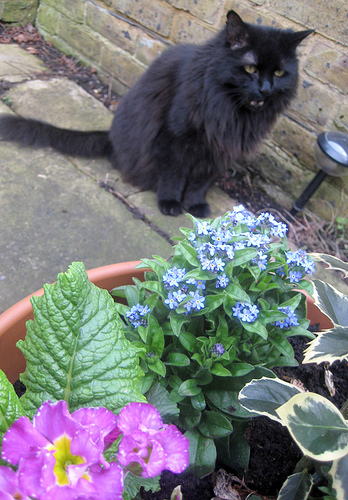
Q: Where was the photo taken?
A: It was taken at the patio.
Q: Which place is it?
A: It is a patio.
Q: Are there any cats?
A: Yes, there is a cat.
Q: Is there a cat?
A: Yes, there is a cat.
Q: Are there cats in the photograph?
A: Yes, there is a cat.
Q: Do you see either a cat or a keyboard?
A: Yes, there is a cat.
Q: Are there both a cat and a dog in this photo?
A: No, there is a cat but no dogs.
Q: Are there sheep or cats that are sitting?
A: Yes, the cat is sitting.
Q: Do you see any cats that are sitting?
A: Yes, there is a cat that is sitting.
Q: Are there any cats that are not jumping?
A: Yes, there is a cat that is sitting.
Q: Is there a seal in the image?
A: No, there are no seals.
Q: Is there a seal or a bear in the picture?
A: No, there are no seals or bears.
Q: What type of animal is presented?
A: The animal is a cat.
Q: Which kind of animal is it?
A: The animal is a cat.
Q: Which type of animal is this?
A: This is a cat.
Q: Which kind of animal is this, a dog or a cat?
A: This is a cat.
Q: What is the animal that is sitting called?
A: The animal is a cat.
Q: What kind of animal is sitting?
A: The animal is a cat.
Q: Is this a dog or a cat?
A: This is a cat.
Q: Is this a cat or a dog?
A: This is a cat.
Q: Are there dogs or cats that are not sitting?
A: No, there is a cat but it is sitting.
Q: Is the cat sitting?
A: Yes, the cat is sitting.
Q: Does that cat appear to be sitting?
A: Yes, the cat is sitting.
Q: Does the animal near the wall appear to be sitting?
A: Yes, the cat is sitting.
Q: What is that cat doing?
A: The cat is sitting.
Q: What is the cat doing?
A: The cat is sitting.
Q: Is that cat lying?
A: No, the cat is sitting.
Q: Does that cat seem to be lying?
A: No, the cat is sitting.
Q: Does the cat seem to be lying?
A: No, the cat is sitting.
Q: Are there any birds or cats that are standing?
A: No, there is a cat but it is sitting.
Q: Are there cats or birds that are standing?
A: No, there is a cat but it is sitting.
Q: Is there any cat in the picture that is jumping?
A: No, there is a cat but it is sitting.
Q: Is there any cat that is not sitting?
A: No, there is a cat but it is sitting.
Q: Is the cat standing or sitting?
A: The cat is sitting.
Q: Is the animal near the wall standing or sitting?
A: The cat is sitting.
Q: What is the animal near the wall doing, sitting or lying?
A: The cat is sitting.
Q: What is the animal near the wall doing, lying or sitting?
A: The cat is sitting.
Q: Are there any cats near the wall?
A: Yes, there is a cat near the wall.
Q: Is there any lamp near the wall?
A: No, there is a cat near the wall.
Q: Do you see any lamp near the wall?
A: No, there is a cat near the wall.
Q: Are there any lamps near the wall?
A: No, there is a cat near the wall.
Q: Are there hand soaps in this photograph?
A: No, there are no hand soaps.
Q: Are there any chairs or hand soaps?
A: No, there are no hand soaps or chairs.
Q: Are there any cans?
A: No, there are no cans.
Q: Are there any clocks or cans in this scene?
A: No, there are no cans or clocks.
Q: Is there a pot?
A: Yes, there is a pot.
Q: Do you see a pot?
A: Yes, there is a pot.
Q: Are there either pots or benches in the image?
A: Yes, there is a pot.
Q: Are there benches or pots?
A: Yes, there is a pot.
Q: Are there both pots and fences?
A: No, there is a pot but no fences.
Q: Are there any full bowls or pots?
A: Yes, there is a full pot.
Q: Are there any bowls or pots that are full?
A: Yes, the pot is full.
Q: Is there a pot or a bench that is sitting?
A: Yes, the pot is sitting.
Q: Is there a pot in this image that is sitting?
A: Yes, there is a pot that is sitting.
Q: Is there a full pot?
A: Yes, there is a full pot.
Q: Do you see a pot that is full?
A: Yes, there is a pot that is full.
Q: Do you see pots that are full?
A: Yes, there is a pot that is full.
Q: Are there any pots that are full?
A: Yes, there is a pot that is full.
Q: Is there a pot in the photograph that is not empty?
A: Yes, there is an full pot.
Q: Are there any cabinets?
A: No, there are no cabinets.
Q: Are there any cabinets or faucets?
A: No, there are no cabinets or faucets.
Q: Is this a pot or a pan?
A: This is a pot.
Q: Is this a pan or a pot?
A: This is a pot.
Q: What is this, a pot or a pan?
A: This is a pot.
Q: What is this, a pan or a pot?
A: This is a pot.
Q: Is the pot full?
A: Yes, the pot is full.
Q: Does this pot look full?
A: Yes, the pot is full.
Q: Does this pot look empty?
A: No, the pot is full.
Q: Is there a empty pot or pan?
A: No, there is a pot but it is full.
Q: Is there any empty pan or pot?
A: No, there is a pot but it is full.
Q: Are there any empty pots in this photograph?
A: No, there is a pot but it is full.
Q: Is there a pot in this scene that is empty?
A: No, there is a pot but it is full.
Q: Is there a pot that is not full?
A: No, there is a pot but it is full.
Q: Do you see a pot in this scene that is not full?
A: No, there is a pot but it is full.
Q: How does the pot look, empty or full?
A: The pot is full.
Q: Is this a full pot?
A: Yes, this is a full pot.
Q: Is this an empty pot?
A: No, this is a full pot.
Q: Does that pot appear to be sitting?
A: Yes, the pot is sitting.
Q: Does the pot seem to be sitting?
A: Yes, the pot is sitting.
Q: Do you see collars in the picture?
A: Yes, there is a collar.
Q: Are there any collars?
A: Yes, there is a collar.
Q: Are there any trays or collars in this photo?
A: Yes, there is a collar.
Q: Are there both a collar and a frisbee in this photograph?
A: No, there is a collar but no frisbees.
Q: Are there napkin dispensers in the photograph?
A: No, there are no napkin dispensers.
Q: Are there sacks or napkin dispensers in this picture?
A: No, there are no napkin dispensers or sacks.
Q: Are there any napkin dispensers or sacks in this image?
A: No, there are no napkin dispensers or sacks.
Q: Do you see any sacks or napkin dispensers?
A: No, there are no napkin dispensers or sacks.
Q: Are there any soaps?
A: No, there are no soaps.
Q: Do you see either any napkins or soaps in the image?
A: No, there are no soaps or napkins.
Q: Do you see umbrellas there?
A: No, there are no umbrellas.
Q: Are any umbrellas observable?
A: No, there are no umbrellas.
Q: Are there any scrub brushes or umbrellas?
A: No, there are no umbrellas or scrub brushes.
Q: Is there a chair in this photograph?
A: No, there are no chairs.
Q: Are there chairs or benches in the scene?
A: No, there are no chairs or benches.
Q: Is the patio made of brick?
A: Yes, the patio is made of brick.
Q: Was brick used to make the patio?
A: Yes, the patio is made of brick.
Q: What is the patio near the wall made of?
A: The patio is made of brick.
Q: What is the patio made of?
A: The patio is made of brick.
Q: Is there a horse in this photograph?
A: No, there are no horses.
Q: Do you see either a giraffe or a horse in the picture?
A: No, there are no horses or giraffes.